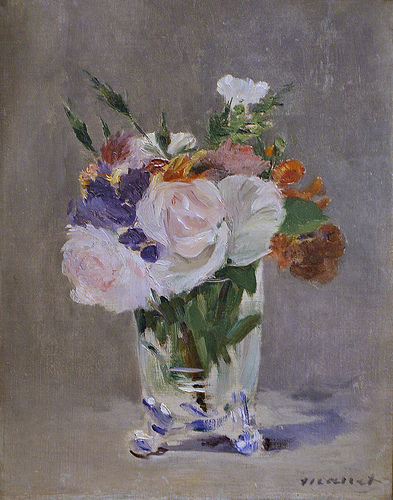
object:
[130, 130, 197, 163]
flowers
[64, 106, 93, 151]
leaves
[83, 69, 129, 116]
leaves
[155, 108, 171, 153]
leaves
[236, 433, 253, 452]
blue highlights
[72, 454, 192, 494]
ground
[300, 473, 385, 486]
name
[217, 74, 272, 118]
flower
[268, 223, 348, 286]
flower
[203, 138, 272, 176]
flower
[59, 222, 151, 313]
flower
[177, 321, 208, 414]
stem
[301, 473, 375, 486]
writing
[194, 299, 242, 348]
leaves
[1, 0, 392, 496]
painting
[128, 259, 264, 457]
vase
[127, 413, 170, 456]
foot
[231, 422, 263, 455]
foot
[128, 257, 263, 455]
glass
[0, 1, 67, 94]
gray area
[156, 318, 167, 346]
leaves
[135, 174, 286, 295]
flower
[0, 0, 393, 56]
taupe background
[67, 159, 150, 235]
flower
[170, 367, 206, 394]
light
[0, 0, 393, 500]
picture